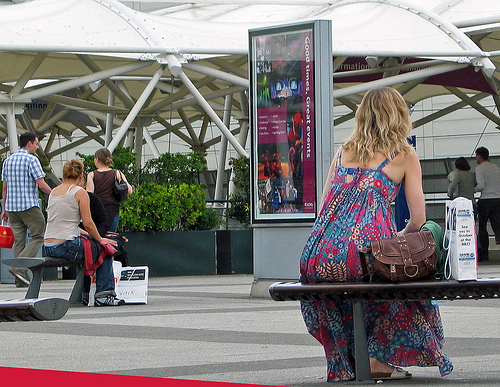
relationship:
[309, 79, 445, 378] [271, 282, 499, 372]
woman on bench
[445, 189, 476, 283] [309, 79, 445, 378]
bag near woman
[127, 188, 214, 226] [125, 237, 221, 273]
shrub in planter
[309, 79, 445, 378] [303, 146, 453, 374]
woman wears dress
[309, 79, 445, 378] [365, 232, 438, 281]
woman has purse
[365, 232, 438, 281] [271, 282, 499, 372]
purse on bench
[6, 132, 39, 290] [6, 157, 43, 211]
man wears shirt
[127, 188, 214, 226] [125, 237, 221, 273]
bush in planter